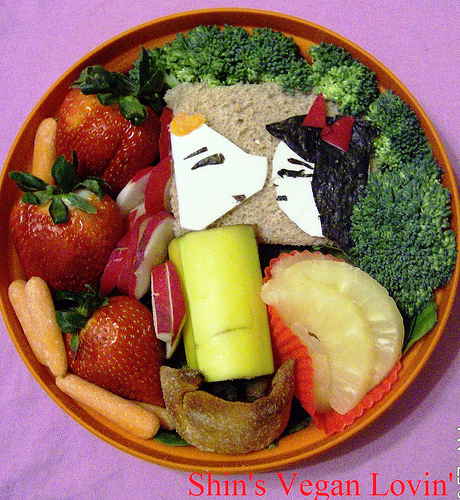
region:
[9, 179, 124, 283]
The strawberries are red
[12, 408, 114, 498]
The table cloth is purple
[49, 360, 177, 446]
The carrots are on the outside of the bowl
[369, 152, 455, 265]
The broccoli is green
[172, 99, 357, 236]
The food has faces on it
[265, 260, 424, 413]
The pine apple is cut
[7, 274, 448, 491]
The food is in a bowl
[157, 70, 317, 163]
The bread is brown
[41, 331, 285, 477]
Fruits and vegetables are in the bowl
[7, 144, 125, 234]
The stems are on the broccoli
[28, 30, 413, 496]
orange colored round plate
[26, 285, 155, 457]
a couple pieces of carrots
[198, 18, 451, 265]
brocolli around the edge of the plate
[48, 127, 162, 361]
red strawberry pieces in bowl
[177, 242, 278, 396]
yellow pieces of pineapple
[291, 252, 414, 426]
cut piece orange slices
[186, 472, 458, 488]
hot pink text logo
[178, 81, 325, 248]
one slice of wheat bread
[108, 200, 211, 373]
cut slices of apples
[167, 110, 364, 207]
piees of cheese made into faces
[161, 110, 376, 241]
the faces on the persons plate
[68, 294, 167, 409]
the strawberry on the plate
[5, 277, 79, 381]
mini carrots on the plate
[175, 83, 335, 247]
paper on the bread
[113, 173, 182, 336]
slices of veggies on the plate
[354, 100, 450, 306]
broccoli on the side of the plate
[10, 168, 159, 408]
veggies and fruit on the plate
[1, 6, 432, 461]
an orange plate with food on it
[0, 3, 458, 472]
the plate with various fruits and vegtebales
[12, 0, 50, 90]
the purple top of the table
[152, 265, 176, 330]
component in tossed salad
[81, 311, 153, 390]
component in tossed salad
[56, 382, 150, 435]
component in tossed salad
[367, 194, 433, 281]
component in tossed salad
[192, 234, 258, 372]
component in tossed salad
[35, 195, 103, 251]
component in tossed salad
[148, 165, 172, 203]
component in tossed salad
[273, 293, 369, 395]
component in tossed salad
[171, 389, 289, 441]
component in tossed salad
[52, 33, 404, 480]
a bowl of salad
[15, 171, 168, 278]
strawberries and apple slices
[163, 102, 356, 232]
two faces kissing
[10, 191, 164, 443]
carrots and strawberries next to each other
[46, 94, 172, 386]
fruit on left side of plate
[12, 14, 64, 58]
a purple background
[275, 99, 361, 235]
a girl with a red bow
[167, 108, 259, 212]
a man with blonde hair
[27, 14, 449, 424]
orange bowl of fruit